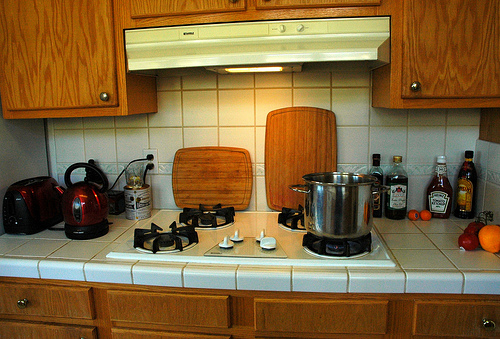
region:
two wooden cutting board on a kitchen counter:
[172, 108, 334, 211]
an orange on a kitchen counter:
[480, 224, 498, 256]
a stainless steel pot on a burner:
[288, 171, 385, 231]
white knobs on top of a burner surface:
[218, 226, 273, 248]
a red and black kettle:
[53, 162, 110, 238]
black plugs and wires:
[110, 154, 154, 187]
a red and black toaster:
[0, 175, 63, 232]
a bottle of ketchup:
[426, 153, 452, 218]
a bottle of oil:
[387, 153, 409, 217]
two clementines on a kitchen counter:
[408, 206, 431, 221]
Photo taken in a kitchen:
[9, 8, 491, 330]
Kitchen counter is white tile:
[9, 207, 484, 292]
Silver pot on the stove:
[290, 170, 380, 241]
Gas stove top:
[122, 197, 405, 272]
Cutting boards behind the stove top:
[173, 104, 354, 206]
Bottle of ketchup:
[423, 152, 456, 216]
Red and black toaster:
[0, 169, 70, 239]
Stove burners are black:
[132, 199, 226, 252]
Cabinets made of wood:
[0, 18, 495, 113]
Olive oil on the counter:
[382, 152, 411, 222]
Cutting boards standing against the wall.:
[169, 98, 339, 223]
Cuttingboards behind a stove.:
[174, 93, 361, 262]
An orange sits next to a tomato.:
[456, 218, 496, 253]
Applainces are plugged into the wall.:
[0, 138, 185, 249]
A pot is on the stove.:
[293, 175, 380, 249]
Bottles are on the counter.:
[351, 150, 498, 204]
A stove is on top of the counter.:
[136, 195, 403, 320]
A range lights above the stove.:
[183, 49, 323, 90]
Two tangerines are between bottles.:
[396, 198, 451, 236]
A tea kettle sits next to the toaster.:
[1, 153, 101, 261]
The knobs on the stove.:
[219, 229, 273, 252]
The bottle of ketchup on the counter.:
[429, 153, 454, 214]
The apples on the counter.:
[460, 216, 479, 251]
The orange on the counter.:
[477, 228, 498, 253]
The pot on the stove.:
[292, 168, 380, 239]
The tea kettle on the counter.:
[52, 162, 113, 240]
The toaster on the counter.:
[3, 173, 63, 230]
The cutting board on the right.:
[266, 109, 348, 211]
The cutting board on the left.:
[172, 143, 252, 208]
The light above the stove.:
[222, 67, 292, 69]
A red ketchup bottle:
[424, 150, 453, 216]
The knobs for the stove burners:
[217, 229, 287, 254]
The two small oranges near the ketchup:
[406, 208, 431, 219]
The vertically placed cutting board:
[267, 106, 337, 210]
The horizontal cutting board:
[168, 145, 252, 210]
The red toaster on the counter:
[5, 174, 68, 232]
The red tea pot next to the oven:
[51, 162, 112, 238]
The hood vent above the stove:
[124, 15, 386, 72]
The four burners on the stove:
[139, 208, 380, 258]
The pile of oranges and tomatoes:
[457, 223, 497, 245]